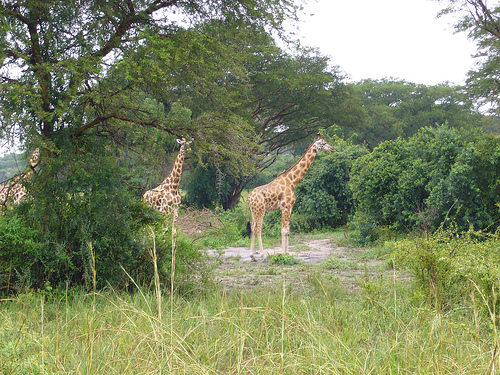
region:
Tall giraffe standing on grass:
[237, 126, 315, 246]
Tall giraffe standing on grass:
[150, 136, 206, 281]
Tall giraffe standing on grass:
[10, 125, 40, 216]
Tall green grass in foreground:
[13, 243, 498, 353]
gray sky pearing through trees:
[296, 6, 476, 100]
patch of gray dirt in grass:
[194, 214, 354, 302]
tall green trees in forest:
[10, 18, 497, 278]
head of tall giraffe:
[310, 120, 337, 164]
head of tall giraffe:
[165, 128, 193, 152]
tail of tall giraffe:
[239, 200, 251, 225]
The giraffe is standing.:
[233, 112, 341, 280]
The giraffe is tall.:
[237, 124, 342, 264]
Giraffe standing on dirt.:
[242, 130, 334, 272]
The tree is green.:
[1, 1, 283, 312]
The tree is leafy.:
[3, 1, 310, 318]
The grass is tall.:
[1, 274, 498, 371]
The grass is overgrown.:
[3, 287, 499, 373]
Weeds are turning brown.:
[3, 204, 498, 372]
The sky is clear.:
[1, 0, 498, 161]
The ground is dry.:
[0, 195, 499, 374]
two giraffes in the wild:
[130, 119, 378, 233]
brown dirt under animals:
[304, 242, 341, 277]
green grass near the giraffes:
[320, 262, 460, 368]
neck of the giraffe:
[280, 145, 315, 180]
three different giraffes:
[1, 92, 381, 259]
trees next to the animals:
[90, 30, 295, 155]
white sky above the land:
[326, 7, 411, 72]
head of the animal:
[305, 125, 340, 160]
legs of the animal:
[240, 220, 310, 260]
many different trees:
[25, 15, 316, 140]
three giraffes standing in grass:
[7, 122, 342, 268]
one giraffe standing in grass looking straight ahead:
[233, 125, 334, 279]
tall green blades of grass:
[118, 258, 254, 374]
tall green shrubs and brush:
[328, 128, 497, 244]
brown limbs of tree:
[72, 109, 179, 139]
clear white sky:
[336, 10, 430, 74]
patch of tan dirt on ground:
[311, 243, 341, 261]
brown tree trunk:
[22, 28, 61, 152]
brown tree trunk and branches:
[211, 93, 321, 211]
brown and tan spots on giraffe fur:
[268, 184, 291, 203]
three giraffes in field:
[7, 158, 346, 267]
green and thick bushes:
[267, 118, 499, 228]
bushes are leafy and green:
[325, 92, 497, 214]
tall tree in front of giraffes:
[14, 1, 194, 239]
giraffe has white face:
[295, 132, 336, 163]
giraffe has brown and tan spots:
[235, 152, 321, 229]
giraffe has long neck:
[258, 135, 326, 191]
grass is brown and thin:
[28, 264, 315, 339]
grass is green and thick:
[341, 232, 492, 374]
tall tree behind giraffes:
[173, 58, 307, 240]